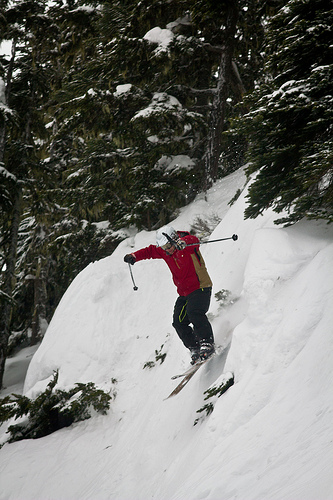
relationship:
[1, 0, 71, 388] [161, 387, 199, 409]
tree in snow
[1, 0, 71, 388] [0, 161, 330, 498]
tree in snow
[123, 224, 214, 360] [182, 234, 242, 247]
man holding ski pole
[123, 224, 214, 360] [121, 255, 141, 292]
man holding ski pole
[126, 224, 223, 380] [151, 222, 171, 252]
man with helmet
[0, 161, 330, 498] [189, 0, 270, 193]
snow with tree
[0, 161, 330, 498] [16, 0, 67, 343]
snow with tree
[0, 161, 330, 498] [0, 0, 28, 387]
snow with tree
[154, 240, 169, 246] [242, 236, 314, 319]
goggles for snow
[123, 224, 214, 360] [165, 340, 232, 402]
man on skis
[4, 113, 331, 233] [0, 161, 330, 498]
trees in snow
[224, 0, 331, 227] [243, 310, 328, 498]
tree in snow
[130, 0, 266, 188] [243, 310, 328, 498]
trees in snow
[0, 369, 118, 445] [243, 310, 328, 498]
tree in snow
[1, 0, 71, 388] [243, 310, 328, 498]
tree in snow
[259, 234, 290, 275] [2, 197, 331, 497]
snow on hillside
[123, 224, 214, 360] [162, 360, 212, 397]
man wearing skis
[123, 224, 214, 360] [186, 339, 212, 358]
man wearing shoes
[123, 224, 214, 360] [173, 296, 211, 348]
man in black pants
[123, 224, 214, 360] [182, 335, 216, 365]
man in boots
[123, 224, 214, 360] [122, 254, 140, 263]
man with black gloves